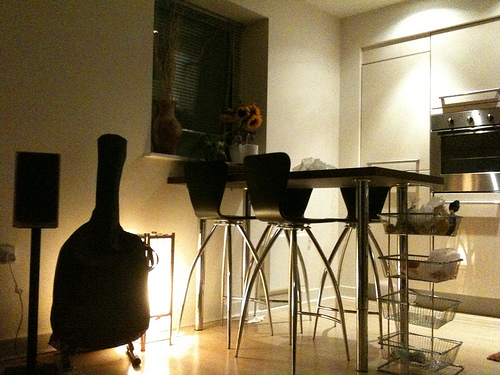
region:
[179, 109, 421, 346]
chairs at a table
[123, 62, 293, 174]
a window in a kitchen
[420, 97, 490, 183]
a oven in a kitchen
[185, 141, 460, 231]
a table in a kitchen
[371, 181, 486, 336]
a steel basket in the kitchen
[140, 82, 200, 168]
a vase near a table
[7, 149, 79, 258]
a speaker near a kitchen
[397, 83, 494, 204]
a steel stove in a kitchen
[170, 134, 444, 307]
four chairs in a kitchen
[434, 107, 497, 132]
knobs on a stove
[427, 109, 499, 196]
a gray wall oven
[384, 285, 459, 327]
a gray basket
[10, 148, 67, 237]
a black speaker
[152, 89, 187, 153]
a large vase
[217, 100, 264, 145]
large yellow sunflowers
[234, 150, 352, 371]
a tall black and gray chair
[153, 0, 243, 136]
the window of a home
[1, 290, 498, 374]
part of a hardwood floor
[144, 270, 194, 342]
a bright light reflection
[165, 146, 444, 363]
a small kitchen table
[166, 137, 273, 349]
the four high stools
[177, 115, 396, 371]
the four high stools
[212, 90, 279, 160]
the flower is yellow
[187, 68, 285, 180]
the flower is yellow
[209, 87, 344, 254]
the flower is yellow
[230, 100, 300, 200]
the flower is yellow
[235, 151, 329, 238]
Black seat of a bar stool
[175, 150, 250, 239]
Black seat of a bar stool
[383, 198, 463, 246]
Small wire basket by a table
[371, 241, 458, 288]
Small wire basket by a table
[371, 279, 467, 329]
Small wire basket by a table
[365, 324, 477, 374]
Small wire basket by a table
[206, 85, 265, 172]
Sunflowers in the window seal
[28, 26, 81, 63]
Part of a white wall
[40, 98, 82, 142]
Part of a white wall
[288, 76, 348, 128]
Part of a white wall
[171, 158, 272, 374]
chair at the table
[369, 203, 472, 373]
baskets on the side of table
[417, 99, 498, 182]
oven in the wall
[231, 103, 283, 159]
flowers in a vase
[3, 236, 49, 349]
outlet in the wall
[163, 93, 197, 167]
vase on the sill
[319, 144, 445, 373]
table has metal legs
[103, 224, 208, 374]
glow on the floor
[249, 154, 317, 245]
back of chairs are black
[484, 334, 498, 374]
rug on the floor